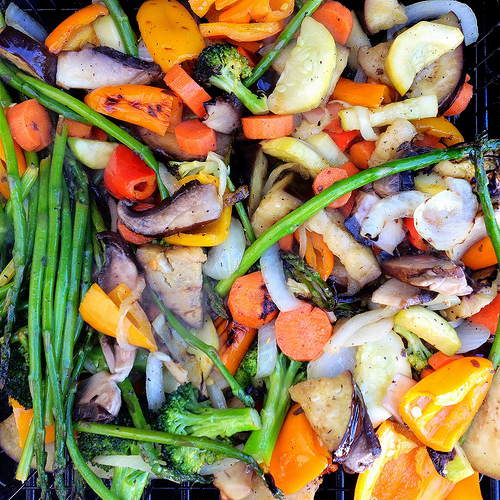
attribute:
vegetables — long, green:
[6, 116, 103, 495]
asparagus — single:
[212, 138, 477, 296]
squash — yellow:
[377, 18, 473, 101]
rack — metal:
[470, 6, 499, 149]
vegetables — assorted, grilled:
[5, 47, 492, 497]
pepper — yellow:
[399, 357, 499, 456]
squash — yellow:
[262, 14, 344, 122]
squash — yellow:
[378, 20, 462, 99]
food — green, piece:
[217, 141, 488, 301]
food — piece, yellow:
[77, 277, 153, 358]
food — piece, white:
[260, 245, 294, 314]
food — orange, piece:
[170, 119, 216, 157]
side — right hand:
[403, 50, 492, 497]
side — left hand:
[1, 0, 175, 497]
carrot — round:
[272, 305, 328, 364]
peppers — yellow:
[400, 357, 492, 457]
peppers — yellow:
[134, 0, 197, 76]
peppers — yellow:
[266, 404, 329, 494]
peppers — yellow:
[79, 281, 158, 361]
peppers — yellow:
[160, 176, 235, 247]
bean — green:
[71, 422, 264, 486]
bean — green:
[18, 73, 162, 179]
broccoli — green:
[156, 383, 261, 477]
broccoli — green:
[77, 420, 139, 459]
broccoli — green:
[194, 45, 270, 119]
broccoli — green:
[246, 352, 303, 458]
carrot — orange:
[271, 303, 333, 364]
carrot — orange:
[171, 116, 221, 163]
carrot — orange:
[8, 96, 47, 156]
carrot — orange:
[240, 110, 291, 142]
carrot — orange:
[308, 165, 354, 212]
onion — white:
[257, 243, 295, 313]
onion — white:
[139, 350, 167, 410]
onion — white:
[388, 2, 482, 48]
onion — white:
[252, 323, 275, 382]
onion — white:
[320, 299, 393, 358]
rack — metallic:
[1, 1, 499, 497]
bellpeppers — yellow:
[360, 386, 493, 497]